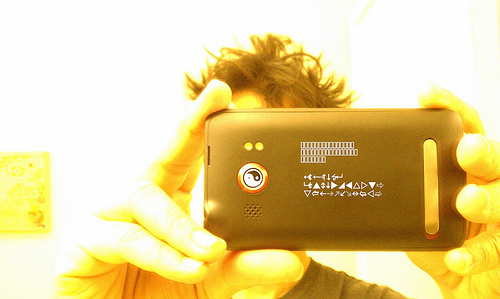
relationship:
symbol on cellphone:
[303, 173, 387, 198] [204, 105, 465, 248]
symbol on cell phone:
[303, 173, 387, 198] [203, 102, 465, 249]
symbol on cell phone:
[303, 173, 387, 198] [168, 94, 474, 256]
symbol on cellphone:
[324, 185, 335, 197] [200, 83, 476, 254]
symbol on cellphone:
[303, 173, 387, 198] [184, 76, 471, 276]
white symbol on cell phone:
[377, 189, 383, 196] [203, 102, 465, 249]